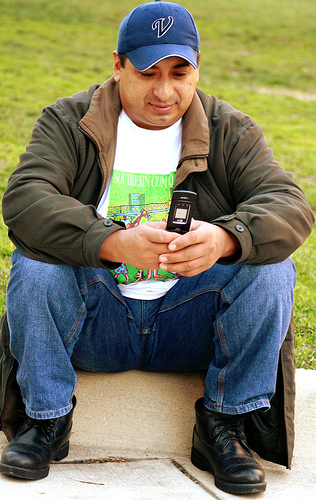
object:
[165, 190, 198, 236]
black cellphone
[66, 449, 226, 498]
crack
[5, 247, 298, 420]
jeans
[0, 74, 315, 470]
coat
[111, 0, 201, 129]
head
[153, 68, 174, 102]
nose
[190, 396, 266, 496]
black shoe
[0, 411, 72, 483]
black shoe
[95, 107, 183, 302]
t shirt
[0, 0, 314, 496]
man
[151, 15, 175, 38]
v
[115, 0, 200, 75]
blue hat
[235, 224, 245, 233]
button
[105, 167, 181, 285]
picture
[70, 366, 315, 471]
curb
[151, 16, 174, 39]
logo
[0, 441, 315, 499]
concrete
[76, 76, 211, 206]
collar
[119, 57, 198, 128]
face